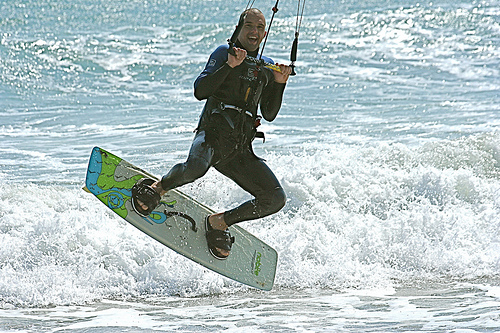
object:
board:
[83, 143, 280, 291]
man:
[135, 7, 293, 258]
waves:
[402, 161, 491, 204]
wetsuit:
[152, 44, 290, 224]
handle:
[224, 46, 298, 75]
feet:
[204, 212, 235, 260]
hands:
[225, 46, 249, 67]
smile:
[237, 19, 267, 48]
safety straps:
[205, 97, 258, 121]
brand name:
[248, 246, 266, 278]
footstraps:
[206, 229, 233, 251]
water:
[0, 0, 498, 328]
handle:
[163, 207, 198, 233]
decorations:
[94, 159, 104, 165]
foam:
[347, 64, 377, 78]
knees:
[182, 154, 211, 182]